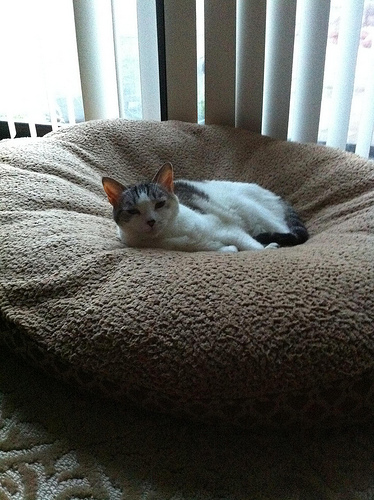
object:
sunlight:
[0, 3, 135, 128]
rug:
[7, 401, 367, 485]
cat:
[101, 162, 308, 249]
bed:
[0, 122, 368, 430]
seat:
[2, 111, 371, 426]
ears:
[100, 161, 173, 201]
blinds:
[2, 2, 371, 123]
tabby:
[100, 161, 307, 254]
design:
[2, 434, 118, 496]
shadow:
[70, 366, 370, 497]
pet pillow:
[0, 116, 372, 405]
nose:
[141, 211, 160, 226]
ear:
[98, 176, 123, 203]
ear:
[151, 160, 174, 191]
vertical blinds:
[137, 1, 366, 135]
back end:
[241, 180, 308, 250]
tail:
[252, 199, 308, 250]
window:
[2, 0, 371, 130]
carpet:
[4, 393, 369, 496]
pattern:
[2, 433, 115, 496]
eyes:
[123, 199, 168, 216]